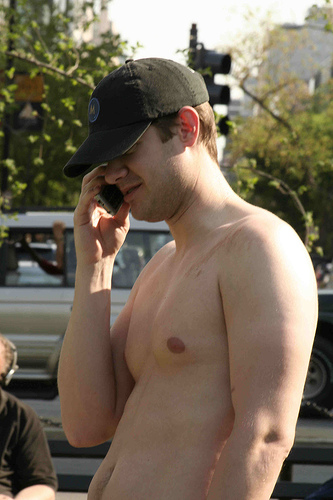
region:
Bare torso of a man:
[84, 208, 316, 496]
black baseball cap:
[59, 55, 207, 172]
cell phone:
[90, 180, 122, 212]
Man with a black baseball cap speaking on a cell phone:
[53, 55, 316, 495]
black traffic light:
[181, 45, 228, 134]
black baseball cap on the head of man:
[62, 55, 219, 222]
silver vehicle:
[3, 210, 175, 397]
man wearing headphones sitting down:
[0, 335, 56, 499]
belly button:
[104, 464, 116, 486]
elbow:
[233, 413, 297, 471]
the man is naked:
[35, 113, 262, 417]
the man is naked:
[37, 0, 323, 319]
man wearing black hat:
[59, 62, 225, 231]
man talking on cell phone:
[78, 143, 142, 234]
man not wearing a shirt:
[57, 224, 319, 496]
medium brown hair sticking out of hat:
[153, 98, 223, 160]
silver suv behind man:
[3, 208, 137, 369]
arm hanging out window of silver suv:
[9, 219, 69, 307]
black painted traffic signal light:
[184, 24, 251, 141]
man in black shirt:
[2, 328, 65, 498]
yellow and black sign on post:
[4, 61, 47, 142]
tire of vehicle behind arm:
[304, 341, 330, 411]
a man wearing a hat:
[60, 24, 296, 246]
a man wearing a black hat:
[28, 28, 314, 261]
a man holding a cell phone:
[42, 16, 332, 281]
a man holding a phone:
[14, 59, 299, 305]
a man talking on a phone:
[22, 37, 303, 301]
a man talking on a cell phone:
[33, 73, 207, 236]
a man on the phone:
[60, 67, 328, 311]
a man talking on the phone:
[24, 42, 300, 315]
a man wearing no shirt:
[22, 16, 327, 377]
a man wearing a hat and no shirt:
[19, 51, 301, 379]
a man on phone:
[38, 54, 315, 277]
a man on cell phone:
[38, 64, 272, 256]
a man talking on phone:
[48, 82, 277, 263]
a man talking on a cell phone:
[28, 113, 249, 306]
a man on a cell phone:
[46, 97, 274, 321]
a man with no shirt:
[25, 35, 259, 498]